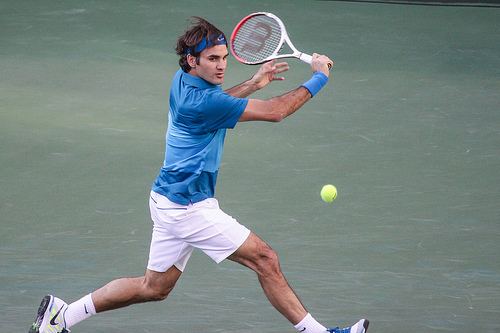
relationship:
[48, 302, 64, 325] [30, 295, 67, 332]
logo on shoe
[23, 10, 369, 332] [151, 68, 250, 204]
man in shirt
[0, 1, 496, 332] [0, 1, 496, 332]
court of court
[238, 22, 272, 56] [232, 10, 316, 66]
w logo on tennis racket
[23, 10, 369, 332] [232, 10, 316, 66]
man holding tennis racket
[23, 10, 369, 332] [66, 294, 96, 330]
man wearing sock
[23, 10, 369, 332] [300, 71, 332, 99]
man has band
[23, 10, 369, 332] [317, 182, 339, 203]
man swing at ball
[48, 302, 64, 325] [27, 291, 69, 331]
logo on shoe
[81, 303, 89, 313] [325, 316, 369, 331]
logo on shoe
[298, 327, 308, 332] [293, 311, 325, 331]
logo on sock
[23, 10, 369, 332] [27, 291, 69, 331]
man wearing shoe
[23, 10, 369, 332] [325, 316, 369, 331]
man wearing shoe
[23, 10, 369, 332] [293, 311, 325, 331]
man wearing sock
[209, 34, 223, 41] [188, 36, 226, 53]
logo on band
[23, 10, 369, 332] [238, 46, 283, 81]
man has hands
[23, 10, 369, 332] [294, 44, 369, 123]
man has hands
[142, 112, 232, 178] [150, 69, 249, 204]
straps trap shirt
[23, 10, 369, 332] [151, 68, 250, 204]
man wearing shirt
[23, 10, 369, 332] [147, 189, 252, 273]
man wearing shorts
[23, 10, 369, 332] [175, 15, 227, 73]
man has hair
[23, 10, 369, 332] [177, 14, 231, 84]
man has head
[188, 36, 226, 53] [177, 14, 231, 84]
band on head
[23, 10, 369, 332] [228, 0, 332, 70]
man holding tennis racket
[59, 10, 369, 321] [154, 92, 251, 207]
man wearing shirt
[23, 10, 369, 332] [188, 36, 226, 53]
man wearing band